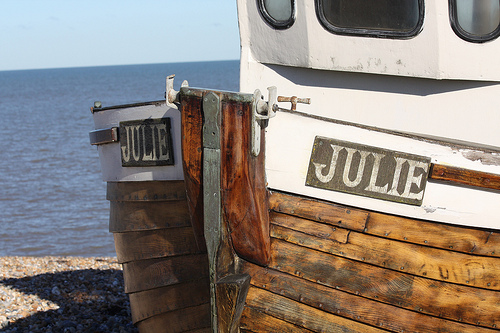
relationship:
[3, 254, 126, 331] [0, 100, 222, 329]
beach of lake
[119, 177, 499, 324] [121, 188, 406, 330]
bottom of boat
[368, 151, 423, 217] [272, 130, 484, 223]
letter on sign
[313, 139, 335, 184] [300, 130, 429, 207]
letter on sign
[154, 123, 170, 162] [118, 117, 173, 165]
letter on sign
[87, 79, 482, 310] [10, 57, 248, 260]
boat next to lake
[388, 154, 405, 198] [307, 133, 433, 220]
letter on sign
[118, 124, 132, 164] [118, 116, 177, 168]
letter on sign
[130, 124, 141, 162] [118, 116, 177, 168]
letter on sign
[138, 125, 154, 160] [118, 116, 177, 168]
letter on sign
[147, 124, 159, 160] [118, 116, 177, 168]
letter on sign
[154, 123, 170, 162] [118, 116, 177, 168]
letter on sign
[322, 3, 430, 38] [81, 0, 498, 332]
windows on boat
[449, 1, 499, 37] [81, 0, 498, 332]
windows on boat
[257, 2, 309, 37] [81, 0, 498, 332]
windows on boat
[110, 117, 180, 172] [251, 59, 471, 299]
boats name on side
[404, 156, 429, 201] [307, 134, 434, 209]
letter on sign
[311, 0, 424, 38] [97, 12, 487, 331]
window on front of boat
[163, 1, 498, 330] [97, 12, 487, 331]
front end of a boat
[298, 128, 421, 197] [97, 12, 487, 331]
name on boat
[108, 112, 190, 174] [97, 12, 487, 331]
name on boat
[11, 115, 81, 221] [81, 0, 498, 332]
water next to boat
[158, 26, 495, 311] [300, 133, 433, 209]
boat has a name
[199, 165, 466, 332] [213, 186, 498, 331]
boat base made of wood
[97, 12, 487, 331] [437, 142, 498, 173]
boat has paint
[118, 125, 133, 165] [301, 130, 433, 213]
letter on sign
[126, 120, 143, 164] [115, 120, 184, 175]
letter on sign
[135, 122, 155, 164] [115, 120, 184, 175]
letter on sign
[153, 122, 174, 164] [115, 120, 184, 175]
letter on sign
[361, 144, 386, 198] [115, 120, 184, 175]
letter on sign